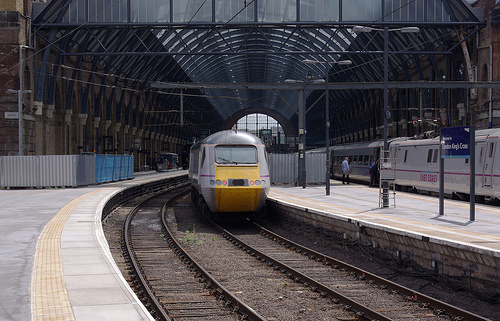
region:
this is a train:
[191, 122, 278, 198]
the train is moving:
[188, 125, 274, 210]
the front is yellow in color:
[213, 166, 260, 205]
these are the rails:
[185, 245, 340, 310]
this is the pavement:
[24, 192, 95, 282]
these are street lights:
[346, 19, 425, 46]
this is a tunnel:
[121, 17, 336, 109]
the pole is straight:
[368, 33, 397, 130]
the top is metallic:
[214, 20, 270, 71]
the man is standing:
[338, 152, 349, 176]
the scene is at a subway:
[1, 1, 498, 314]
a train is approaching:
[185, 126, 272, 221]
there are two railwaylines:
[132, 244, 441, 316]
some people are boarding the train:
[369, 152, 382, 182]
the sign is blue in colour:
[440, 118, 477, 186]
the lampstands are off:
[293, 21, 489, 66]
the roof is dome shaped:
[38, 3, 499, 128]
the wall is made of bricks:
[11, 97, 37, 153]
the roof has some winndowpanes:
[58, 2, 425, 22]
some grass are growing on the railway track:
[179, 230, 224, 243]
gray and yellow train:
[181, 123, 281, 227]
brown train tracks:
[100, 162, 496, 319]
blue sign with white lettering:
[437, 123, 474, 163]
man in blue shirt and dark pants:
[339, 153, 356, 189]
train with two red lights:
[191, 125, 286, 227]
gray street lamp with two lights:
[351, 19, 423, 208]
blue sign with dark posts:
[428, 113, 489, 228]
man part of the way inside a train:
[367, 158, 381, 187]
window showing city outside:
[225, 103, 286, 152]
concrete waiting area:
[1, 151, 197, 318]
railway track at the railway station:
[154, 222, 369, 316]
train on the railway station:
[188, 128, 268, 208]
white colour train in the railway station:
[357, 136, 498, 197]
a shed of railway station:
[133, 12, 396, 126]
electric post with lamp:
[350, 17, 418, 212]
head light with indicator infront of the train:
[207, 176, 267, 186]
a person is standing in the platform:
[340, 150, 352, 184]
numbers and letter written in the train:
[414, 165, 446, 185]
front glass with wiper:
[210, 143, 265, 165]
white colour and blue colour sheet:
[18, 157, 136, 179]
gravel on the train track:
[209, 246, 252, 280]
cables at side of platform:
[333, 226, 440, 275]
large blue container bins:
[87, 142, 149, 179]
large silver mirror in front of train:
[208, 139, 263, 166]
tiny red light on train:
[221, 177, 230, 188]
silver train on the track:
[195, 129, 279, 209]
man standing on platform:
[336, 152, 358, 185]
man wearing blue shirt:
[338, 160, 355, 169]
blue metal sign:
[421, 118, 488, 217]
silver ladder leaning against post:
[367, 141, 407, 211]